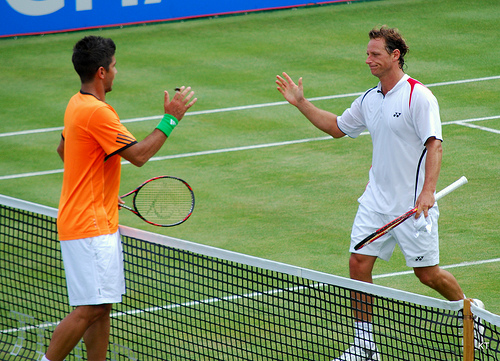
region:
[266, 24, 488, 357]
man in white shirt and shorts going to shake the hand of the man in orange shirt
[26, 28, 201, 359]
man in orange shirt ready to shake hand of man in white shirt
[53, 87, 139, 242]
orange shirt the man is wearing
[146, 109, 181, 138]
green sweat band on mans arm with orange shirt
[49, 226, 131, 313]
white shorts the man in the orange shirt is weaing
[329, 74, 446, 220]
white shirt with black and red design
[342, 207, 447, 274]
white short on the man with white shirt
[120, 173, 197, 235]
tennis racquet of the man with orange shirt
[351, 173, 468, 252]
tennis racquet of the man with white shirt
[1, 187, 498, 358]
tennis net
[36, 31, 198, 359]
male tennis player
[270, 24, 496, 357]
male tennis player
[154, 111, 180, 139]
green wristband on a tennis player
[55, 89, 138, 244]
orange shirt on a tennis player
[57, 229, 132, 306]
white shorts on a tennis player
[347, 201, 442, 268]
white shorts on a tennis player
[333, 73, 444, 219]
white shirt on a tennis player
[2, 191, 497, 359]
tennis net in between two tennis players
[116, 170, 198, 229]
tennis racket held by a tennis player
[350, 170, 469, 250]
tennis racket held by a tennis player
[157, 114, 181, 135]
a green wristband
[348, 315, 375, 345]
a man's white sock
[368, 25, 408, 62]
a man's short cut brown hair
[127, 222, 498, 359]
part of a black and white tennis net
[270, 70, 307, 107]
the hand of a man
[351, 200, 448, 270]
a man's white shorts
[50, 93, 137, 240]
a man's orange shirt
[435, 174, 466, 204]
a white racket handle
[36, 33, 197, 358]
tennis player in orange shirt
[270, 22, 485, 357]
tennis player in all white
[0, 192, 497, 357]
the net between the two players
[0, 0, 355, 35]
a blue wall in the background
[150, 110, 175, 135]
green sweatband on a player's wrist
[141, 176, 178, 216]
logo on a tennis racket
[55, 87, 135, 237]
orange shirt on one player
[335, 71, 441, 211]
white shirt on player on right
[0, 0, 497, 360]
the green tennis court the players are on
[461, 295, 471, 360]
a pole holding the net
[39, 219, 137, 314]
man wearing white shorts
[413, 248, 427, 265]
black logo on white shorts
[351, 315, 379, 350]
man wearing white socks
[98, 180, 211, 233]
man holding a tennis racket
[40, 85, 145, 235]
man wearing a orange shirt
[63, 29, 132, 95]
man with black hair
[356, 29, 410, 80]
man with blonde hair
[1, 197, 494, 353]
tennis net on the court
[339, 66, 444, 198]
man wearing a white shirt